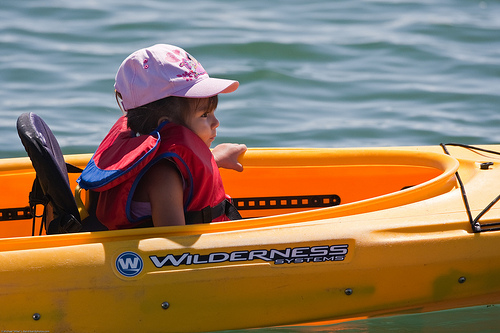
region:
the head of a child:
[110, 40, 225, 150]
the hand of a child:
[208, 135, 253, 175]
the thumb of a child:
[228, 155, 248, 174]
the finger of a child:
[232, 141, 250, 157]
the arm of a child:
[142, 158, 189, 226]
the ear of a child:
[156, 110, 173, 127]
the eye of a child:
[197, 106, 212, 122]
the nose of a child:
[208, 113, 221, 133]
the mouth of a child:
[204, 132, 220, 144]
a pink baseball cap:
[108, 40, 243, 118]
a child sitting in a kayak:
[7, 2, 464, 312]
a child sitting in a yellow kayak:
[42, 28, 445, 296]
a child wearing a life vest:
[59, 41, 296, 250]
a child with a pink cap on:
[107, 40, 245, 159]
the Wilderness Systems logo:
[146, 238, 366, 273]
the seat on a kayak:
[10, 109, 90, 231]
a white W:
[111, 252, 148, 281]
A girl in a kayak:
[98, 39, 279, 246]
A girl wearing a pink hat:
[111, 32, 240, 127]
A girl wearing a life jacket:
[72, 48, 277, 243]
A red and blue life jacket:
[75, 113, 258, 232]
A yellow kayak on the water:
[4, 44, 499, 329]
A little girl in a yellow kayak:
[2, 21, 498, 325]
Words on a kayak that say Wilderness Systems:
[144, 231, 359, 280]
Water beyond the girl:
[22, 14, 479, 139]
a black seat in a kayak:
[17, 108, 104, 239]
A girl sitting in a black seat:
[6, 35, 283, 247]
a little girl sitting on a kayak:
[83, 43, 249, 228]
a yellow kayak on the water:
[0, 144, 497, 331]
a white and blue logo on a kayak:
[116, 248, 143, 276]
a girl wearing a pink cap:
[109, 39, 241, 109]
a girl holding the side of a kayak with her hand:
[206, 140, 253, 173]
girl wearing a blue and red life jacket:
[78, 108, 241, 228]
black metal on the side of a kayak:
[0, 193, 339, 220]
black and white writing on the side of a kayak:
[148, 242, 349, 268]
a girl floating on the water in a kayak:
[1, 45, 496, 330]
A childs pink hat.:
[114, 43, 239, 113]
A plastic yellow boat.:
[1, 143, 499, 332]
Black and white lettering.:
[149, 240, 352, 268]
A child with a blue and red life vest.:
[75, 45, 247, 229]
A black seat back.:
[13, 110, 84, 236]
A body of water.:
[0, 0, 499, 157]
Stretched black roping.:
[441, 138, 499, 234]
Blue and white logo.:
[114, 249, 142, 277]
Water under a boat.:
[213, 301, 499, 331]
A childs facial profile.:
[126, 93, 222, 150]